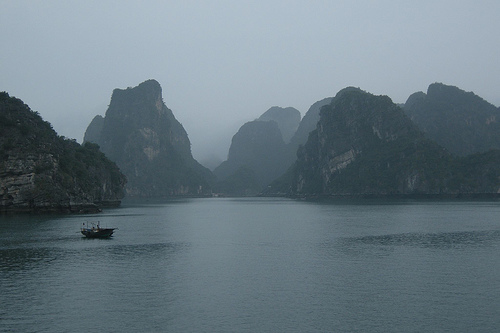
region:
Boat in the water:
[63, 214, 147, 259]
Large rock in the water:
[399, 56, 469, 130]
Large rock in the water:
[290, 66, 496, 237]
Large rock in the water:
[207, 91, 295, 213]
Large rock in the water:
[81, 77, 227, 214]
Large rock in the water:
[1, 76, 128, 224]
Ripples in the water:
[371, 289, 420, 331]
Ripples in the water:
[325, 233, 389, 280]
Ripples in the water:
[195, 193, 286, 252]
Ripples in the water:
[143, 272, 206, 310]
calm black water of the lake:
[218, 239, 350, 293]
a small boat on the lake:
[73, 215, 122, 242]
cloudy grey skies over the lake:
[213, 30, 273, 78]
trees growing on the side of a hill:
[329, 128, 450, 192]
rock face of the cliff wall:
[0, 157, 51, 212]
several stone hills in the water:
[0, 73, 451, 218]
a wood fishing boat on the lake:
[81, 216, 118, 240]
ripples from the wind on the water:
[36, 249, 127, 271]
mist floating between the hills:
[184, 118, 311, 175]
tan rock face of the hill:
[319, 148, 359, 188]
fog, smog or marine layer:
[193, 115, 223, 155]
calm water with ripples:
[179, 265, 337, 320]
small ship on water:
[82, 220, 116, 240]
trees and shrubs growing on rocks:
[52, 137, 109, 197]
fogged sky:
[148, 13, 403, 52]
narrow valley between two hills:
[185, 135, 239, 180]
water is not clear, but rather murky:
[166, 225, 328, 300]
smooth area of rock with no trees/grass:
[328, 153, 361, 168]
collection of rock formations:
[109, 78, 494, 200]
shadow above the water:
[360, 230, 492, 255]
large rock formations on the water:
[21, 58, 498, 287]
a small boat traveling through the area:
[66, 212, 150, 257]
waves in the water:
[314, 214, 498, 269]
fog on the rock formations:
[47, 69, 478, 166]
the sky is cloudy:
[35, 18, 425, 94]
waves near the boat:
[8, 203, 194, 266]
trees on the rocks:
[11, 93, 136, 208]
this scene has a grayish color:
[42, 29, 474, 301]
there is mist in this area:
[16, 17, 467, 289]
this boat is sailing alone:
[47, 206, 168, 256]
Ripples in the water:
[20, 292, 77, 329]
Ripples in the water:
[82, 291, 129, 330]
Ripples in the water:
[130, 287, 156, 327]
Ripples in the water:
[148, 284, 243, 330]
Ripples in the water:
[233, 269, 289, 329]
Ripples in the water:
[283, 269, 338, 328]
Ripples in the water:
[341, 274, 392, 331]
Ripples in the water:
[386, 271, 430, 327]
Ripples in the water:
[431, 272, 464, 317]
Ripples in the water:
[295, 236, 372, 285]